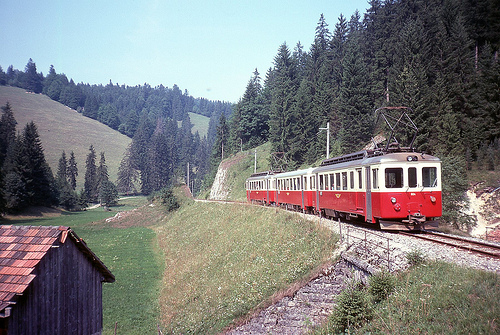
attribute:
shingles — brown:
[3, 223, 60, 307]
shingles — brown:
[6, 221, 85, 325]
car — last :
[238, 148, 442, 236]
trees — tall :
[223, 9, 470, 142]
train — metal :
[237, 148, 449, 229]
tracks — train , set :
[415, 223, 484, 255]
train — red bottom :
[238, 138, 441, 240]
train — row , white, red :
[246, 143, 445, 233]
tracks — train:
[405, 215, 483, 255]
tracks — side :
[410, 220, 484, 256]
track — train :
[194, 192, 483, 258]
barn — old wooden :
[4, 207, 118, 326]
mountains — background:
[5, 63, 226, 183]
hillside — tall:
[4, 60, 219, 185]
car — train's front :
[372, 140, 445, 233]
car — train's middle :
[275, 158, 318, 212]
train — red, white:
[241, 144, 440, 245]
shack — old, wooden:
[0, 214, 100, 334]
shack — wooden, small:
[4, 229, 119, 334]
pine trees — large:
[86, 92, 256, 190]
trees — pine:
[230, 63, 410, 165]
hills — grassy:
[180, 98, 387, 316]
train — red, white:
[276, 148, 449, 250]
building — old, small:
[12, 213, 138, 332]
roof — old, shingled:
[0, 234, 75, 288]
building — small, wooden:
[2, 216, 115, 332]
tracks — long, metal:
[293, 204, 494, 270]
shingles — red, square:
[5, 210, 66, 274]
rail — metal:
[395, 221, 493, 261]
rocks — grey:
[289, 230, 468, 265]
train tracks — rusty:
[404, 222, 494, 255]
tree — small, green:
[93, 179, 121, 208]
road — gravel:
[81, 199, 100, 212]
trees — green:
[18, 60, 160, 132]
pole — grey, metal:
[317, 120, 339, 158]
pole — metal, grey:
[248, 143, 262, 182]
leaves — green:
[331, 82, 365, 114]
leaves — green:
[292, 92, 305, 142]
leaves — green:
[404, 89, 424, 149]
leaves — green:
[440, 77, 462, 120]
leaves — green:
[166, 194, 176, 209]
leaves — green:
[156, 149, 165, 191]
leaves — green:
[101, 182, 111, 204]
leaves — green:
[89, 167, 103, 194]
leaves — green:
[27, 142, 49, 190]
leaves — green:
[97, 186, 109, 199]